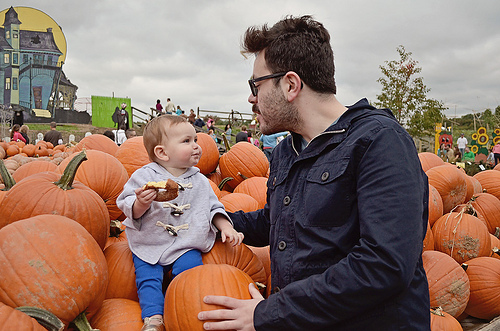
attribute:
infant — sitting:
[115, 108, 247, 330]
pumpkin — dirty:
[1, 210, 112, 330]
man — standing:
[164, 95, 177, 118]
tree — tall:
[369, 37, 428, 135]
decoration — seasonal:
[108, 98, 132, 133]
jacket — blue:
[213, 99, 433, 330]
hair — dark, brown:
[241, 9, 342, 94]